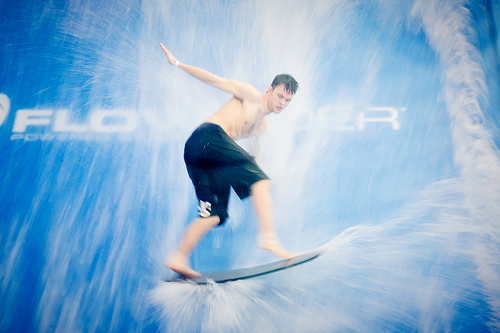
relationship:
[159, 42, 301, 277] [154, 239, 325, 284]
boy in surfboard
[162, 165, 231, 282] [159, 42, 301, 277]
left leg under boy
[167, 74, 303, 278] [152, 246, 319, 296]
boy on surfboard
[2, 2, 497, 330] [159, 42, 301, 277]
water under boy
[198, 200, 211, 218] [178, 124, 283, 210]
design on shorts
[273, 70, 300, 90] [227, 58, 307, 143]
dark hair on boy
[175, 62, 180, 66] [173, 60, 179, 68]
wristband on wrist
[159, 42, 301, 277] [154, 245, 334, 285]
boy on surfboard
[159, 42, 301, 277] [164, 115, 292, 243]
boy wearing trunks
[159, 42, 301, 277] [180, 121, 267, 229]
boy wearing shorts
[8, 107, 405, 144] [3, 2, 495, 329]
sign on wall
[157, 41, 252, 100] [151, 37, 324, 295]
arm on surfer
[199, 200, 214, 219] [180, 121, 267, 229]
design on shorts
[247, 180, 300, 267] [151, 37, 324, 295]
leg on surfer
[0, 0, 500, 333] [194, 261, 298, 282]
water splashing from a surfboard